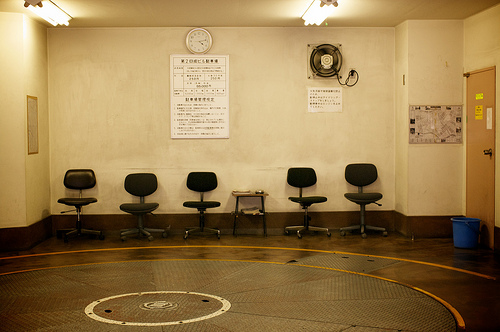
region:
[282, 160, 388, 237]
Two chairs side-by-side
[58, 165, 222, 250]
Three chairs in a line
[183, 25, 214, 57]
White clock on the wall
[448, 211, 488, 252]
Blue bucket on the floor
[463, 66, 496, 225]
Closed wooden door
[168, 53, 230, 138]
Sign on wall below clock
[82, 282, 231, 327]
White circle on the floor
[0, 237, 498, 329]
Dark flow with yellow lines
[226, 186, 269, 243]
Small table between two chairs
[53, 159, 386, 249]
Five chairs against the wall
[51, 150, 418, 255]
chairs sitting on the ground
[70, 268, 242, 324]
white circle on the ground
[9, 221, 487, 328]
yellow circle on the ground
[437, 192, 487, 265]
blue bucket on the ground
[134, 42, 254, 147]
poster hanging on the wall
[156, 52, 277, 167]
the poster is white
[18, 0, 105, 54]
lights hanging on the ceiling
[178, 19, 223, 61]
clock hanging on the wall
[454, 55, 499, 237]
brown door to leave the room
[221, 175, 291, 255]
table in between the chairs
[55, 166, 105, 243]
A black office chair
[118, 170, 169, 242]
A black desk chair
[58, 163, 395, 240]
A row of office desk chairs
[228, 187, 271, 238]
A small table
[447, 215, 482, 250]
A blue round bucket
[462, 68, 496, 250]
A wood door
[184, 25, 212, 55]
A wall hanging clock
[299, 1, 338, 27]
A ceiling light fixture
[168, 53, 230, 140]
A wall hanging poster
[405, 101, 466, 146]
Safety floor plan poster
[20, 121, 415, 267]
5 black office chairs in an office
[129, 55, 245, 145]
Asian language sign on a white wall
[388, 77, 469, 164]
Directory on a white wall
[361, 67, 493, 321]
Door to warehouse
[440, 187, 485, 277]
Small blue trashcan in warehouse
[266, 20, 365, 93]
Fan on a white wall in a warehouse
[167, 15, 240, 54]
White clock on a white wall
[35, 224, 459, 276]
Yellow lines on a warehouse floor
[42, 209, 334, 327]
White circle on a warehouse floor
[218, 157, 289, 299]
Small table in a warehouse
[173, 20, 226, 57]
A clock on a wall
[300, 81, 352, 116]
A black and white sign on the wall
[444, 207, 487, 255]
A blue basket on the floor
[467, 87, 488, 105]
A yellow sign on the door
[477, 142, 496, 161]
A metal door handle on a wooden door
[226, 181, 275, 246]
A table against the wall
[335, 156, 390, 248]
An office chair against a wall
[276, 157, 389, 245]
Two chairs against the wall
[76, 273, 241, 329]
A white circle painted on the floor